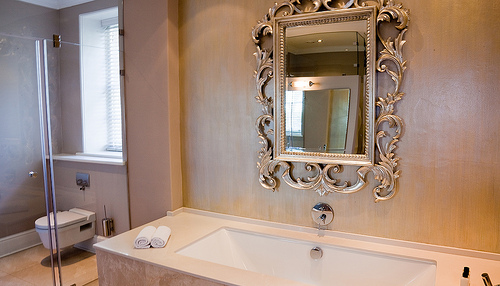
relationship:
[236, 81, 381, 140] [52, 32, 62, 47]
glass room divider with metal bracket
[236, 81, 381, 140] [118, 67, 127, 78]
glass room divider with metal bracket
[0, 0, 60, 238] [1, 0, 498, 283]
wall in bathroom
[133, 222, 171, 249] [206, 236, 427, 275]
towels on tub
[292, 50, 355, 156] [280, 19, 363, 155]
reflection in glass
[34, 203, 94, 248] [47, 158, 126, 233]
toilet attached to wall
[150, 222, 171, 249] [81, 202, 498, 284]
towels on sink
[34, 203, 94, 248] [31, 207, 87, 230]
toilet with lid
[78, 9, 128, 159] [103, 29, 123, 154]
window with blinds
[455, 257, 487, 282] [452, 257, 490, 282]
small bottles with black lids